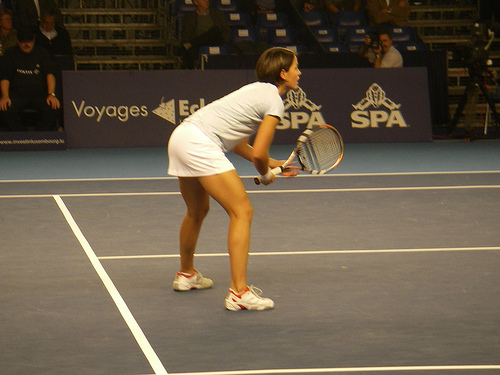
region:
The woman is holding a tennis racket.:
[147, 40, 352, 315]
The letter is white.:
[68, 94, 87, 120]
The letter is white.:
[79, 104, 96, 119]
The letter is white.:
[344, 107, 371, 132]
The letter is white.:
[368, 107, 390, 131]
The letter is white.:
[384, 106, 410, 130]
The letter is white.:
[139, 99, 151, 121]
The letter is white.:
[115, 102, 130, 128]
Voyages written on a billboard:
[67, 92, 149, 122]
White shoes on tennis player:
[170, 265, 275, 310]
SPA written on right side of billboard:
[345, 105, 405, 130]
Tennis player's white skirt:
[151, 120, 231, 180]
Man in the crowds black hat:
[15, 22, 37, 37]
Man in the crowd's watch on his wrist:
[45, 85, 55, 95]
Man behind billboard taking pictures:
[355, 30, 400, 60]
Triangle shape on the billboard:
[150, 90, 180, 125]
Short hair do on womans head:
[255, 41, 300, 87]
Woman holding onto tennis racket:
[166, 46, 346, 313]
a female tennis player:
[158, 45, 358, 312]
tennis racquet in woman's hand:
[258, 120, 351, 191]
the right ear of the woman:
[275, 62, 292, 82]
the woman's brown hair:
[256, 46, 293, 76]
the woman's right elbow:
[248, 151, 264, 166]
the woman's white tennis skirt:
[163, 126, 234, 178]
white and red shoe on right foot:
[225, 278, 278, 313]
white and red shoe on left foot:
[167, 267, 215, 292]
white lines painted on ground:
[0, 184, 168, 373]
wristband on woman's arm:
[262, 170, 277, 182]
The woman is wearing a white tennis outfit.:
[141, 40, 356, 327]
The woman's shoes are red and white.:
[154, 42, 349, 321]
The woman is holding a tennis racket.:
[151, 44, 350, 328]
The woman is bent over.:
[142, 43, 356, 325]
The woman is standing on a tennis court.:
[7, 42, 499, 374]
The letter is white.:
[287, 104, 309, 133]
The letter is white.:
[306, 106, 328, 133]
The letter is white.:
[348, 107, 369, 132]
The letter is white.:
[365, 103, 391, 132]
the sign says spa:
[327, 88, 417, 125]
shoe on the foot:
[229, 289, 271, 308]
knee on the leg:
[230, 198, 252, 218]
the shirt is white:
[245, 87, 269, 107]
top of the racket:
[305, 132, 341, 154]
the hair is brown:
[260, 49, 283, 71]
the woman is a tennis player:
[139, 51, 355, 315]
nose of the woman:
[290, 68, 303, 78]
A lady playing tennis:
[170, 55, 325, 330]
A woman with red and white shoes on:
[163, 253, 258, 325]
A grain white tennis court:
[324, 175, 443, 334]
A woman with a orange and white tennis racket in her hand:
[181, 118, 364, 245]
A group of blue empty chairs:
[251, 19, 326, 59]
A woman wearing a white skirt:
[158, 95, 260, 192]